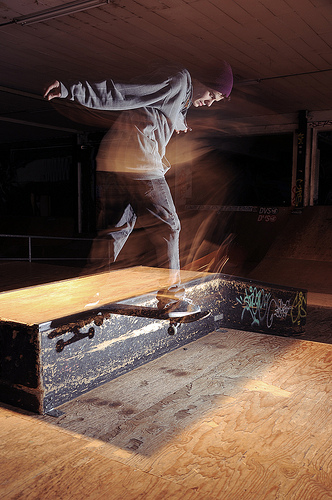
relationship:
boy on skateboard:
[37, 52, 246, 320] [64, 303, 219, 339]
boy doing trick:
[37, 52, 246, 320] [5, 0, 327, 492]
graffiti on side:
[229, 278, 316, 329] [225, 275, 305, 339]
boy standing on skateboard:
[37, 52, 246, 320] [64, 303, 219, 339]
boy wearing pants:
[37, 52, 246, 320] [79, 170, 181, 308]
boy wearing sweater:
[37, 52, 246, 320] [60, 62, 193, 172]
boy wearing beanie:
[37, 52, 246, 320] [190, 53, 238, 100]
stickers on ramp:
[183, 201, 280, 222] [160, 197, 328, 294]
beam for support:
[0, 262, 223, 326] [66, 295, 229, 337]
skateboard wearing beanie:
[92, 300, 212, 336] [190, 53, 238, 100]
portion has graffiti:
[192, 275, 324, 333] [229, 278, 316, 329]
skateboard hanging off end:
[64, 303, 219, 339] [32, 299, 160, 407]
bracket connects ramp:
[45, 406, 66, 423] [2, 261, 222, 326]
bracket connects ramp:
[217, 324, 235, 336] [2, 261, 222, 326]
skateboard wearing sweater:
[92, 300, 212, 336] [60, 62, 193, 172]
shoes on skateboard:
[88, 296, 204, 323] [64, 303, 219, 339]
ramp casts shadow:
[2, 261, 222, 326] [193, 323, 324, 405]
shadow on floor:
[193, 323, 324, 405] [4, 330, 331, 491]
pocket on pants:
[124, 170, 157, 202] [75, 170, 188, 308]